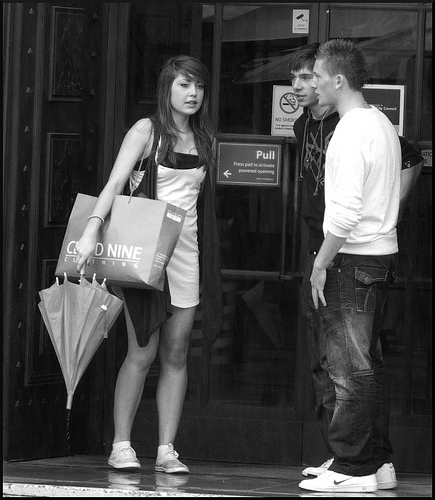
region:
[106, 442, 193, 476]
Sneakers on her feet.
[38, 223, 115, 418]
Arm holding an umbrella.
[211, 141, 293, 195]
Sign on the door.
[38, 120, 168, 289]
Girl carrying a shopping bag.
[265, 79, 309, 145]
Sign on door advising no smoking.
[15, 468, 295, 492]
Wet sidewalk due to rain.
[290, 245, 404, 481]
Man wearing blue jeans.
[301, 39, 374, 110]
Very short haircut.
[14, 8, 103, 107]
Decorative entrance to the store.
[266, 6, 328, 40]
Notice for security cameras.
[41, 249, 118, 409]
girl is carrying an umbrella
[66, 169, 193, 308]
girl is carrying a store bag on her shoulder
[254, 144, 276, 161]
Pull is written on the sign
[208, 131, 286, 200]
sign is on the door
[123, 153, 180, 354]
girl is carrying a purse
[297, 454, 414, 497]
white sneaker's on the guy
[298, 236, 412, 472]
guy is wearing blue jeans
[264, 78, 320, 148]
NO SMOKING sign on the door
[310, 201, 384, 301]
guy pushed his sleeve up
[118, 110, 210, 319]
girl is wearing a dress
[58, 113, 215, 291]
A shopping bag on the woman's shoulder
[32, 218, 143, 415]
An umbrella in the woman's hand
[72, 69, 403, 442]
Two men talking to a shopping woman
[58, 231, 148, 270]
White writing on the woman's shopping bag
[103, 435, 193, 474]
Small grey shoes on the woman's feet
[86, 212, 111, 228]
A small bracelet on the woman's arm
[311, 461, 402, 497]
White sneakers on the man's feet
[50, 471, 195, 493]
Wet concrete under the girl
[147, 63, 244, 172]
The girl has long hair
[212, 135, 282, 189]
A "pull" sign on the glass door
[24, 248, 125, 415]
an umbrella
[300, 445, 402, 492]
nike sneakers worn by a man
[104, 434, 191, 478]
tennis shoes worn by a young woman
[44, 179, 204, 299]
a bag of clothing from Cloud Nine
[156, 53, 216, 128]
a young woman's face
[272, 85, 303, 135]
a no smoking sign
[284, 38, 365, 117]
two young men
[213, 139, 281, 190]
a sign on a door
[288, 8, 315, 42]
a sign warning about security cameras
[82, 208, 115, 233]
a bracelet worn by a young woman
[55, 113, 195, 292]
Young girl carrying box over shoulder.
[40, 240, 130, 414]
Young girl holding umbrella in hand.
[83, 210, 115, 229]
Young girl wearing braclet on wrist.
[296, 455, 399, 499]
Young boy wearing white Nike tennis shoes.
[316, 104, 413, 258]
Young man dressed in white long sleeve shirt.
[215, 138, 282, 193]
Sign on door showing directions.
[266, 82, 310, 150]
No smoking sign on door of business.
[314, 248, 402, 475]
Young man dressed in blue jeans.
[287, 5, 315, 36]
Sign on business door indicating camera.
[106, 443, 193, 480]
Young girl wearing tennis shoes on feet.